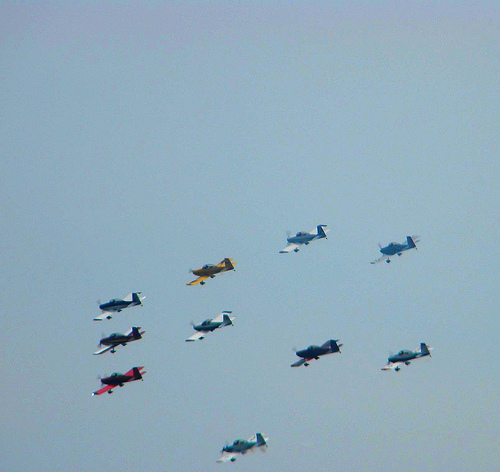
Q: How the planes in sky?
A: Flying.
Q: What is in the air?
A: Planes.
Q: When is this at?
A: During the day time.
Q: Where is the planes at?
A: Bottom of image.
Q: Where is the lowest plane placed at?
A: Center.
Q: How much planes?
A: 10.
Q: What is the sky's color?
A: Blue.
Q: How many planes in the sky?
A: 10.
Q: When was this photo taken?
A: Daytime.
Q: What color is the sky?
A: Blue.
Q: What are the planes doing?
A: Flying.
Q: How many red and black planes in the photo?
A: 1.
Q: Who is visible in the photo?
A: No one.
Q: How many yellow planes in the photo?
A: 1.